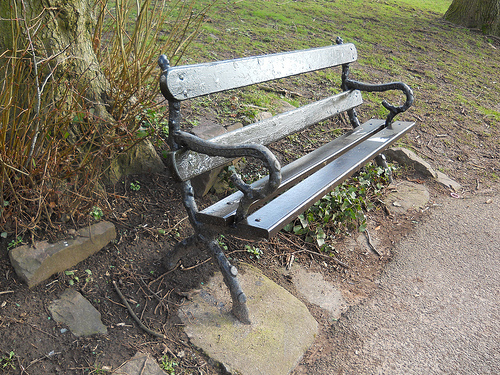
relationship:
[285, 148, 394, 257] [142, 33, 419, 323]
shrub under bench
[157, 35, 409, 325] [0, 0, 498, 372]
bench on ground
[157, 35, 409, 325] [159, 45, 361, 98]
bench has top part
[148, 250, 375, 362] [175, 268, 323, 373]
rocks on side of pavement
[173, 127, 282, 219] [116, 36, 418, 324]
arm rest on bench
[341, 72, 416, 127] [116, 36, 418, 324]
arm rest on bench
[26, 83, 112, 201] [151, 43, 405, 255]
tree trunk behind bench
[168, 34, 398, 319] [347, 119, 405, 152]
bench on shadow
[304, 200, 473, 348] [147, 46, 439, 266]
pathway in front of bench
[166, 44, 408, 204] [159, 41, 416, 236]
planks of a bench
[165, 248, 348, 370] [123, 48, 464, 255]
pavers around bench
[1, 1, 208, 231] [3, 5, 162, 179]
grass around treetrunk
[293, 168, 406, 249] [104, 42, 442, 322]
weeds underneath bench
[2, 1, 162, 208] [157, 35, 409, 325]
tree behind bench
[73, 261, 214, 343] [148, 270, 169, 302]
sticks on ground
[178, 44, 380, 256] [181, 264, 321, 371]
bench on slabs